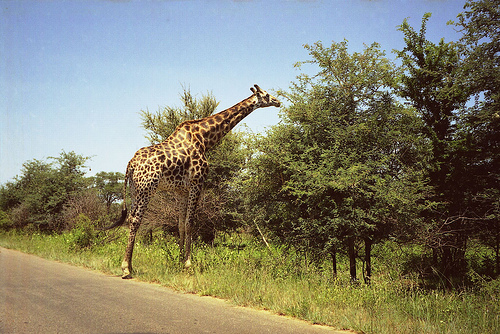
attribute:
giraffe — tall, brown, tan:
[114, 71, 288, 282]